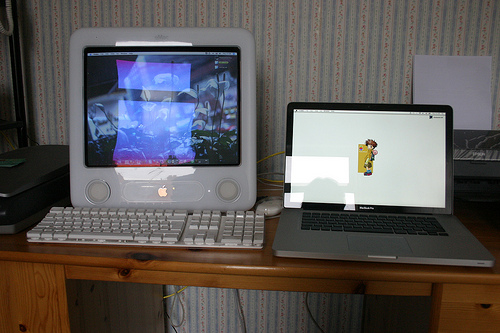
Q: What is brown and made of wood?
A: Computer desk.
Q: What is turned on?
A: Computer.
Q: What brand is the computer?
A: Apple.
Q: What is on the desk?
A: Laptop computer.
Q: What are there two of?
A: Computers.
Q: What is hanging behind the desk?
A: Power cords.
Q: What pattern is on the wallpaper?
A: Blue stripes with flowers.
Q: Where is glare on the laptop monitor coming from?
A: Sunlight from a window.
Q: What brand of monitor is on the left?
A: Apple.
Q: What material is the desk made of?
A: Wood.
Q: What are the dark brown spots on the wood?
A: Knots in the wood.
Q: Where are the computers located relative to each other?
A: Side by side.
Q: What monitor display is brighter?
A: The laptop's.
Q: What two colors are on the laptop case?
A: Black and silver.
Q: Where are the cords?
A: Under the desk.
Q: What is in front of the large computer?
A: A keyboard.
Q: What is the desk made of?
A: Wood.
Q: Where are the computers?
A: On the desk.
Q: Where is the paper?
A: Against the wall.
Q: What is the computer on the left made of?
A: Plastic.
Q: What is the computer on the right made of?
A: Metal and plastic.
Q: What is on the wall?
A: Wallpaper.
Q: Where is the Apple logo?
A: On the computer on the left.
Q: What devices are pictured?
A: Computers.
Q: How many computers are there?
A: Two.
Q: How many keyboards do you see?
A: Two.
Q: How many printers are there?
A: One.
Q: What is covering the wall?
A: Wallpaper.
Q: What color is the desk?
A: Brown.